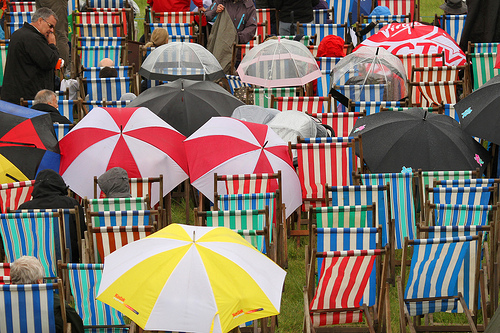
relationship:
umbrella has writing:
[96, 218, 292, 333] [110, 290, 144, 318]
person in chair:
[7, 255, 82, 333] [1, 277, 70, 333]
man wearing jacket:
[4, 8, 64, 102] [2, 23, 58, 102]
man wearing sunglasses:
[4, 8, 64, 102] [41, 19, 55, 30]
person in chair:
[17, 170, 86, 262] [9, 205, 82, 260]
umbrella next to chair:
[184, 115, 306, 220] [284, 142, 354, 209]